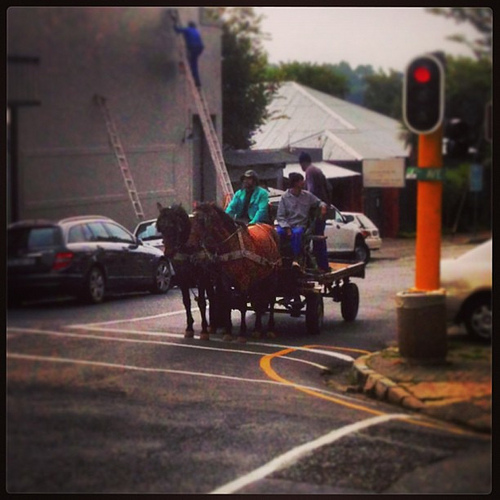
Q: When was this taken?
A: During the day.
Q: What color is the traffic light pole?
A: Red.